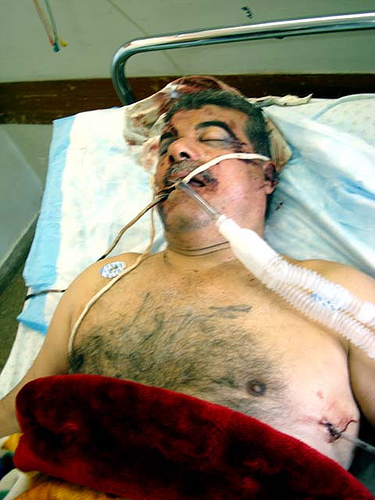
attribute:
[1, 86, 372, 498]
man — in pain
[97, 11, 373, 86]
bar — metal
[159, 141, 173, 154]
eye — black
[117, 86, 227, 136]
rag — bloody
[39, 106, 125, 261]
cloth — hospital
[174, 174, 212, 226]
machine tube — bendable, for breathing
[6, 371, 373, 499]
fabric — red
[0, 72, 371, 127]
board — brown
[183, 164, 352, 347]
tube — into his side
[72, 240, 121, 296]
electrical patch — lead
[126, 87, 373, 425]
male — older